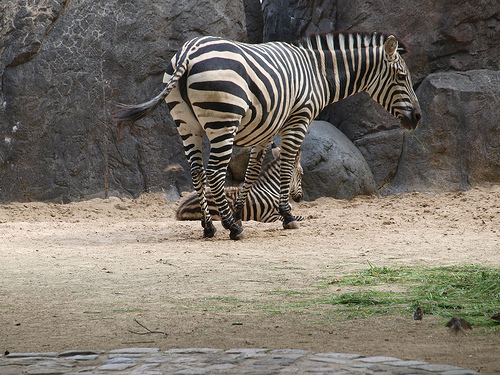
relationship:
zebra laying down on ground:
[174, 147, 309, 225] [3, 193, 497, 372]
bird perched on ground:
[414, 303, 424, 321] [3, 193, 497, 372]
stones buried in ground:
[1, 346, 476, 374] [3, 193, 497, 372]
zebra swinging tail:
[131, 33, 421, 236] [129, 56, 195, 125]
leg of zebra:
[207, 116, 254, 234] [131, 33, 421, 236]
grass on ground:
[353, 261, 500, 318] [3, 193, 497, 372]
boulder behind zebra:
[423, 76, 499, 185] [131, 33, 421, 236]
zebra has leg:
[131, 33, 421, 236] [207, 116, 254, 234]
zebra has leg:
[131, 33, 421, 236] [181, 126, 217, 236]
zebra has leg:
[131, 33, 421, 236] [282, 114, 303, 229]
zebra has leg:
[131, 33, 421, 236] [236, 143, 264, 230]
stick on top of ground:
[127, 319, 172, 344] [3, 193, 497, 372]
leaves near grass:
[230, 316, 253, 330] [353, 261, 500, 318]